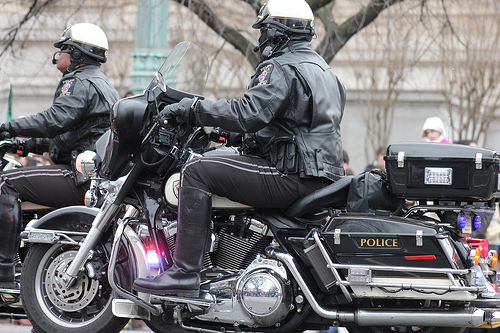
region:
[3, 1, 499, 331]
two police officers riding motorcycles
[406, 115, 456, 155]
person watching the police officers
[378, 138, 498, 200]
carrying case on the back of a motorcycle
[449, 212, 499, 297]
tail lights on the back of the motorcycle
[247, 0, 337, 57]
white and black helmet on the officer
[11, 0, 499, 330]
two police officers watching over traffic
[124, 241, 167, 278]
flashing lights on the front of the motorcycle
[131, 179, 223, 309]
leather boot on the police officer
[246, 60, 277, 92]
patch on the leather jacket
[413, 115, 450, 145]
girl in a white hood watching the police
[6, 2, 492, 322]
two police officers riding on motorcycles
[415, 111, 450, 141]
a woman in the background with a white shawl on her head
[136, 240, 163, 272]
flashing red and blue emergency light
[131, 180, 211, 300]
a shiny black knee-high boot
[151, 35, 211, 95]
windshield of the motorcycle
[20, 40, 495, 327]
a black and silver police motorcyclce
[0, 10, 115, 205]
a policeman wearing a headset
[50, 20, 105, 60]
a black and white police helmet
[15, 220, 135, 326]
black front tire of a motorcycle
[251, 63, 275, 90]
red, blue, and black emblem on the officer's jacket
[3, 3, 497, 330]
Two police mans on their own motorcycle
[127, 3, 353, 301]
police man wearing white and black helmet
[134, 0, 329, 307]
police man wearing black leather jacket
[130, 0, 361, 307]
police man wearing black pants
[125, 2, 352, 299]
police man wearing black gloves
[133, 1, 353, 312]
police man wearing black shoes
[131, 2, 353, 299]
police man wearing black boots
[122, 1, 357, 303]
police man holding on to motorcycle handles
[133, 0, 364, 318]
police man sitting on motorcycle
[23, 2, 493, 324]
police man driving a motorcycle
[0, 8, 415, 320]
Two police officers on motorcycles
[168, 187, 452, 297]
Police motorcycle with officer driving it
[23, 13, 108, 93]
Police officer with helmet and radio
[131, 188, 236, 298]
Tall black boots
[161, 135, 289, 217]
Black uniform pants with gray stripes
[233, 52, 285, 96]
Patch on sleeve of jacket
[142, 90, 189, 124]
Black leather glove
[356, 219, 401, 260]
The word POLICE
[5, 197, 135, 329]
Front wheel of motorcycle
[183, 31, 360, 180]
Black leather jacket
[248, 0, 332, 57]
white and black helmet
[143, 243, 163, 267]
red and blue lights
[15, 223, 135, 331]
black rubber tire for a motorcycle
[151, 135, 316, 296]
black riding pants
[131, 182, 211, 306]
black riding boots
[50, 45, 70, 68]
a microphone on the helmet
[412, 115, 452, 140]
a person in a white hood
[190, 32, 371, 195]
a black leather jacket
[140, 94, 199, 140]
black riding gloves